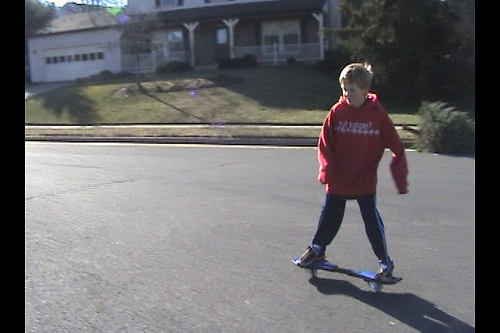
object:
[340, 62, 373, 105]
head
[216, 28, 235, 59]
door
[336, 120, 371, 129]
pattern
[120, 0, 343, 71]
house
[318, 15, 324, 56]
post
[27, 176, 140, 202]
crack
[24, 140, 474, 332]
street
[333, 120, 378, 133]
writing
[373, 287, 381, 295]
wheel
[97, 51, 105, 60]
windows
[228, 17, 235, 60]
white post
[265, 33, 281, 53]
window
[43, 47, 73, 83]
garage door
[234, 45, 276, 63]
white railing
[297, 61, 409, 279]
child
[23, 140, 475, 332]
asphalt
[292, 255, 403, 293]
skateboard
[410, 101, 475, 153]
tree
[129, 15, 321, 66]
porch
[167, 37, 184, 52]
window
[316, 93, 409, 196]
shirt